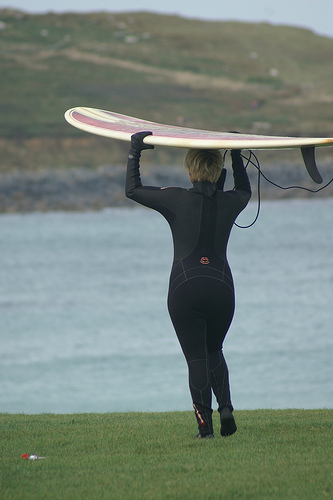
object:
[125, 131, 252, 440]
lady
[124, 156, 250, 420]
suit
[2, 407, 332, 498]
grass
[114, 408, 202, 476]
ground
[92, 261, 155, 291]
water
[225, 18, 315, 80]
hill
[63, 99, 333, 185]
surfboard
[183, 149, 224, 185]
head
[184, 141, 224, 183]
hair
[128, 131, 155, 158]
glove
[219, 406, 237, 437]
shoe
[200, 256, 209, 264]
item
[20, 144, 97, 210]
wall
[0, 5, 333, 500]
scene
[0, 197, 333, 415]
ocean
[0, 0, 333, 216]
background